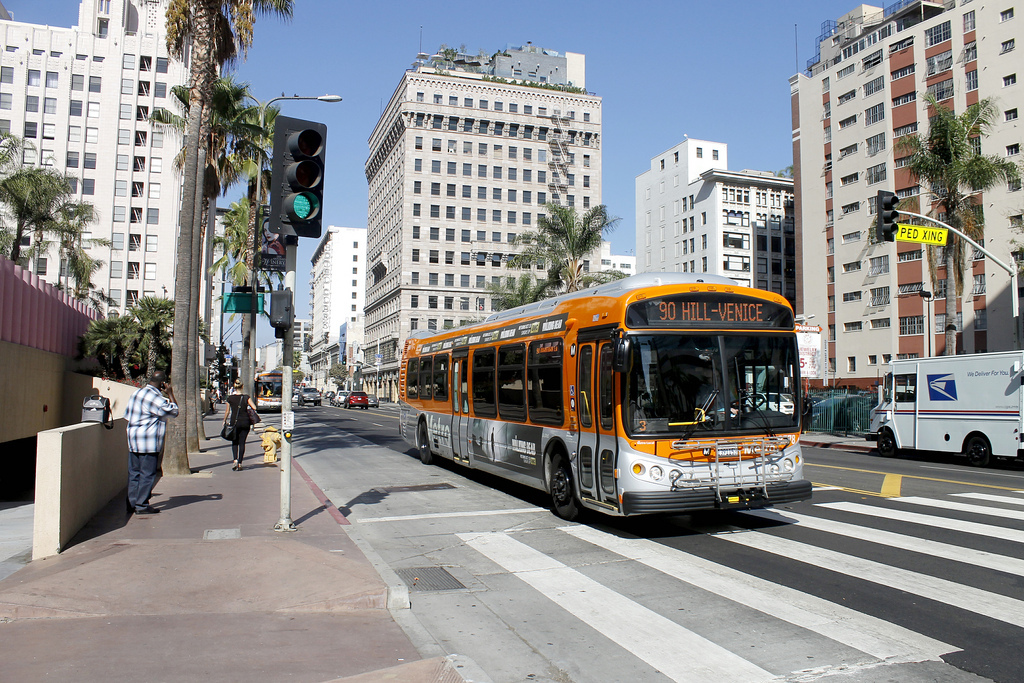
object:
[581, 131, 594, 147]
window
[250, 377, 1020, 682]
street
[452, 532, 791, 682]
line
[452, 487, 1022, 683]
line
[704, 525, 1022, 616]
line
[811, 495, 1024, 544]
line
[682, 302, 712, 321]
word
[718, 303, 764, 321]
word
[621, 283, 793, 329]
board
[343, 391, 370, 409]
car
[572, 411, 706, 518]
rack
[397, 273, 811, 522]
bus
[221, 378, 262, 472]
woman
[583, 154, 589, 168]
window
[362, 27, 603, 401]
building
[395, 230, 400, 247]
window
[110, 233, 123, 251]
window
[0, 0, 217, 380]
building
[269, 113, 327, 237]
traffic light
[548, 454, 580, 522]
tire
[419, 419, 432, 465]
tire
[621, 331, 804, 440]
windshield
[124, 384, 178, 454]
shirt